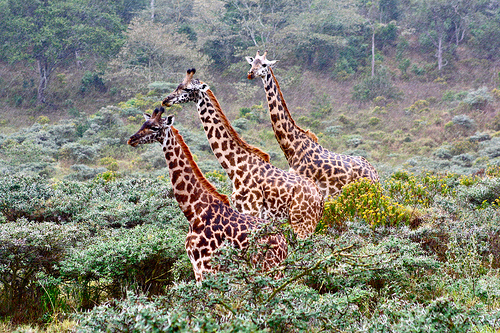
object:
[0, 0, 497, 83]
forest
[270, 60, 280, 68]
ear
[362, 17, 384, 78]
tree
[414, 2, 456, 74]
tree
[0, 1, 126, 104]
tree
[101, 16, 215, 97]
tree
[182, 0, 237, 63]
tree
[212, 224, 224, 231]
shape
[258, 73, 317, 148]
neck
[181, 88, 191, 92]
eye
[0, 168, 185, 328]
plants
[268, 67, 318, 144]
mane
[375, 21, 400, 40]
branches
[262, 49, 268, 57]
horn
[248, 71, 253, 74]
nose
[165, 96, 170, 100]
nose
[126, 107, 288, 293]
giraffe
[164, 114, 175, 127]
ear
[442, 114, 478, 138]
plant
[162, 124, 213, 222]
neck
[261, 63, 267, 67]
eye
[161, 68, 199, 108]
head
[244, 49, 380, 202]
giraffes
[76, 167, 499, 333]
bushes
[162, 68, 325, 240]
giraffe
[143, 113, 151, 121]
ears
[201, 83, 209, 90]
ears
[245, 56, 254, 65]
ears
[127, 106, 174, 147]
head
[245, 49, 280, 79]
head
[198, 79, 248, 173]
neck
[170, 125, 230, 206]
hair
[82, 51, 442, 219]
distance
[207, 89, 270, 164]
mane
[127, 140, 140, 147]
mouth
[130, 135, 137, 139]
nose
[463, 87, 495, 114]
trees